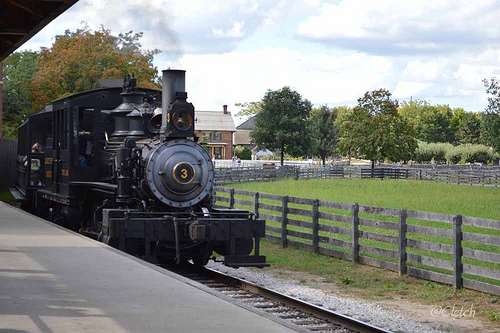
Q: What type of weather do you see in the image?
A: It is cloudy.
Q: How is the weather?
A: It is cloudy.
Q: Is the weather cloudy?
A: Yes, it is cloudy.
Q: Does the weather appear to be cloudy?
A: Yes, it is cloudy.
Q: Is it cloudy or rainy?
A: It is cloudy.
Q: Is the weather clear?
A: No, it is cloudy.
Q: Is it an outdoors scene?
A: Yes, it is outdoors.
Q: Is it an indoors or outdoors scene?
A: It is outdoors.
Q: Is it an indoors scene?
A: No, it is outdoors.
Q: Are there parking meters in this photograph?
A: No, there are no parking meters.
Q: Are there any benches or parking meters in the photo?
A: No, there are no parking meters or benches.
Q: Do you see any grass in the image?
A: Yes, there is grass.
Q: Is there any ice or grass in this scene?
A: Yes, there is grass.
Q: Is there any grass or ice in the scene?
A: Yes, there is grass.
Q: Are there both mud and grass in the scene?
A: No, there is grass but no mud.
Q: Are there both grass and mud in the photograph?
A: No, there is grass but no mud.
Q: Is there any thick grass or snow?
A: Yes, there is thick grass.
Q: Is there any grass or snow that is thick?
A: Yes, the grass is thick.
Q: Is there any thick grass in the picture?
A: Yes, there is thick grass.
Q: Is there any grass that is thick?
A: Yes, there is grass that is thick.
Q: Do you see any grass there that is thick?
A: Yes, there is grass that is thick.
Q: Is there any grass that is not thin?
A: Yes, there is thick grass.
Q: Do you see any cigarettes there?
A: No, there are no cigarettes.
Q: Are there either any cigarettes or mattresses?
A: No, there are no cigarettes or mattresses.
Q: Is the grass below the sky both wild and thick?
A: Yes, the grass is wild and thick.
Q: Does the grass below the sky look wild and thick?
A: Yes, the grass is wild and thick.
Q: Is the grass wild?
A: Yes, the grass is wild.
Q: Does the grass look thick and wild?
A: Yes, the grass is thick and wild.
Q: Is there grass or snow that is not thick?
A: No, there is grass but it is thick.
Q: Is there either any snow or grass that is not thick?
A: No, there is grass but it is thick.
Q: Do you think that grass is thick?
A: Yes, the grass is thick.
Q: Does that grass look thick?
A: Yes, the grass is thick.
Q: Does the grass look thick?
A: Yes, the grass is thick.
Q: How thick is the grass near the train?
A: The grass is thick.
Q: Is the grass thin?
A: No, the grass is thick.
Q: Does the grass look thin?
A: No, the grass is thick.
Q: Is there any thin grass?
A: No, there is grass but it is thick.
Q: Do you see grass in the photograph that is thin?
A: No, there is grass but it is thick.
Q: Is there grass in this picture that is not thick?
A: No, there is grass but it is thick.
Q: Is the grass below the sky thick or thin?
A: The grass is thick.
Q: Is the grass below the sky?
A: Yes, the grass is below the sky.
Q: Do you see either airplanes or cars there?
A: No, there are no cars or airplanes.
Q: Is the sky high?
A: Yes, the sky is high.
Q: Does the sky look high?
A: Yes, the sky is high.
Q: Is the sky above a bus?
A: No, the sky is above the train.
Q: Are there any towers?
A: No, there are no towers.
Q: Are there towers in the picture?
A: No, there are no towers.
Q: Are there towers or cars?
A: No, there are no towers or cars.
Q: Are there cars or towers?
A: No, there are no towers or cars.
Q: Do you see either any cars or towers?
A: No, there are no towers or cars.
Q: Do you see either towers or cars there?
A: No, there are no towers or cars.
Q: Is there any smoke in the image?
A: Yes, there is smoke.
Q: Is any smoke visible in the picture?
A: Yes, there is smoke.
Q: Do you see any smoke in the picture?
A: Yes, there is smoke.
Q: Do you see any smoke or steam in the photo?
A: Yes, there is smoke.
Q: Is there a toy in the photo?
A: No, there are no toys.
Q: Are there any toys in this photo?
A: No, there are no toys.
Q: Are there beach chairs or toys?
A: No, there are no toys or beach chairs.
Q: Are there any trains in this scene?
A: Yes, there is a train.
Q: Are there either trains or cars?
A: Yes, there is a train.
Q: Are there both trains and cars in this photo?
A: No, there is a train but no cars.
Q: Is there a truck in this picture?
A: No, there are no trucks.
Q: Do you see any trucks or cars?
A: No, there are no trucks or cars.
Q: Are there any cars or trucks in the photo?
A: No, there are no trucks or cars.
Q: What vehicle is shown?
A: The vehicle is a train.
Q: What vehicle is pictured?
A: The vehicle is a train.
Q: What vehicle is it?
A: The vehicle is a train.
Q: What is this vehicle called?
A: This is a train.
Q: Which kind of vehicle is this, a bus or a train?
A: This is a train.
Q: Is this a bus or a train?
A: This is a train.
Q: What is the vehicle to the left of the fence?
A: The vehicle is a train.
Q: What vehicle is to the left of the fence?
A: The vehicle is a train.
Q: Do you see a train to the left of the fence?
A: Yes, there is a train to the left of the fence.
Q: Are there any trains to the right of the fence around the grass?
A: No, the train is to the left of the fence.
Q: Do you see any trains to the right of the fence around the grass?
A: No, the train is to the left of the fence.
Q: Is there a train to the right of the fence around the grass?
A: No, the train is to the left of the fence.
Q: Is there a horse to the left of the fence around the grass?
A: No, there is a train to the left of the fence.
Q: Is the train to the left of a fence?
A: Yes, the train is to the left of a fence.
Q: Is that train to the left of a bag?
A: No, the train is to the left of a fence.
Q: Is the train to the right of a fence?
A: No, the train is to the left of a fence.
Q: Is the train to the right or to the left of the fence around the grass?
A: The train is to the left of the fence.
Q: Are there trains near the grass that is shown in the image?
A: Yes, there is a train near the grass.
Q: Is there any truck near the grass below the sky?
A: No, there is a train near the grass.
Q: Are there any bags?
A: No, there are no bags.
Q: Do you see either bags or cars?
A: No, there are no bags or cars.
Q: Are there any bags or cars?
A: No, there are no bags or cars.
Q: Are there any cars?
A: No, there are no cars.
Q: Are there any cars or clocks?
A: No, there are no cars or clocks.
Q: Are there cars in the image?
A: No, there are no cars.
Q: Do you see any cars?
A: No, there are no cars.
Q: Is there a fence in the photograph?
A: Yes, there is a fence.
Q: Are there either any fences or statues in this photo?
A: Yes, there is a fence.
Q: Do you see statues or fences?
A: Yes, there is a fence.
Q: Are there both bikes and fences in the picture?
A: No, there is a fence but no bikes.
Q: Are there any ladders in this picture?
A: No, there are no ladders.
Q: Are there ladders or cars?
A: No, there are no ladders or cars.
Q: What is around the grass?
A: The fence is around the grass.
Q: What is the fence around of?
A: The fence is around the grass.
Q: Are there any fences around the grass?
A: Yes, there is a fence around the grass.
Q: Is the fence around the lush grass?
A: Yes, the fence is around the grass.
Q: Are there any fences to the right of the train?
A: Yes, there is a fence to the right of the train.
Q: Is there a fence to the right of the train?
A: Yes, there is a fence to the right of the train.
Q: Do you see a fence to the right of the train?
A: Yes, there is a fence to the right of the train.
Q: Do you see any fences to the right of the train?
A: Yes, there is a fence to the right of the train.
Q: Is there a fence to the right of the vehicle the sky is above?
A: Yes, there is a fence to the right of the train.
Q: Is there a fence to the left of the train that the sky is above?
A: No, the fence is to the right of the train.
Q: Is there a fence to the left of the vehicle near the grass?
A: No, the fence is to the right of the train.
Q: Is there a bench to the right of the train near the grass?
A: No, there is a fence to the right of the train.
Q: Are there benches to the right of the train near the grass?
A: No, there is a fence to the right of the train.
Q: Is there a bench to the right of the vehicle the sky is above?
A: No, there is a fence to the right of the train.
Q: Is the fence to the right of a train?
A: Yes, the fence is to the right of a train.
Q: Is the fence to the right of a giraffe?
A: No, the fence is to the right of a train.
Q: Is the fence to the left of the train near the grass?
A: No, the fence is to the right of the train.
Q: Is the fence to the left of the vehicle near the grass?
A: No, the fence is to the right of the train.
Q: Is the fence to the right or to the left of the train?
A: The fence is to the right of the train.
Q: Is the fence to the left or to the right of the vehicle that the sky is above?
A: The fence is to the right of the train.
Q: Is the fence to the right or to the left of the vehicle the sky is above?
A: The fence is to the right of the train.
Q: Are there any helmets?
A: No, there are no helmets.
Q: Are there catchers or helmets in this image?
A: No, there are no helmets or catchers.